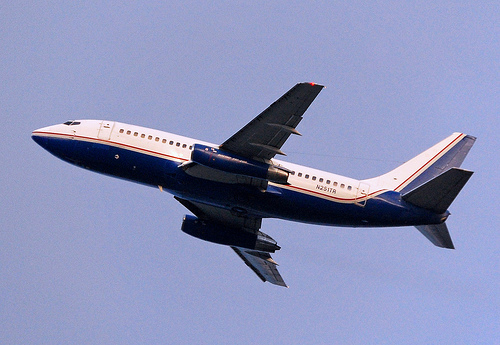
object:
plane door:
[95, 121, 115, 141]